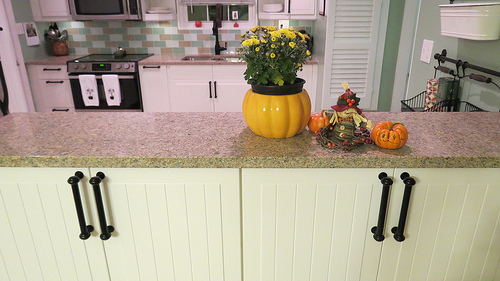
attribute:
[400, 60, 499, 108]
hangers — side by side, black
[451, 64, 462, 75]
line — present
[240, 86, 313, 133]
vase — yellow, pumpkin, beautiful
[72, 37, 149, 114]
stove — glass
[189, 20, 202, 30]
fruit — presented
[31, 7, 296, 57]
wall — green, tiled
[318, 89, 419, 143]
vegetables — present, grouped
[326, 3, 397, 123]
door — white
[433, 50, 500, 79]
rod — iron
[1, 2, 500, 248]
kitchen — decorated, displayed, beautiful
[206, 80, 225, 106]
hardware — black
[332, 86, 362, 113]
hat — red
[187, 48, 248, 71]
tub — white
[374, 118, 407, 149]
gourd — mini, small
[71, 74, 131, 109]
hand towels — presnt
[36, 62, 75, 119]
drawers — white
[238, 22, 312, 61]
flowers — bouquet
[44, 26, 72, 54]
container — present